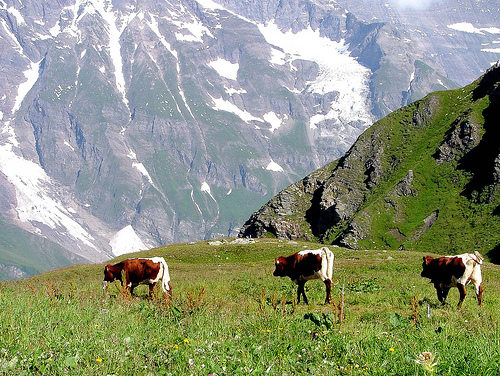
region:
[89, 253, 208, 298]
Cow grazing in the grass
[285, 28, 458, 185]
Snow on side of the mountain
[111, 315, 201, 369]
Flowers and weeds in the grass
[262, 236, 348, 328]
Brown and white cow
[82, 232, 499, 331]
Three cows walking in a row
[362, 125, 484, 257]
Hill is rocky with grass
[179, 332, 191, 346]
Yellow flower in the grass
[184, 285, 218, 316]
Dry weeds in the grass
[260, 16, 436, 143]
Snow in the crack of rocks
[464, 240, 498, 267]
Cow has a long tail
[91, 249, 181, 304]
a brown and white cow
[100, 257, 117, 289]
the head of a cow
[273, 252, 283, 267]
the ear of a cow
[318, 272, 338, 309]
the hind legs of a cow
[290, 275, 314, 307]
the front legs of a cow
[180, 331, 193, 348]
a yellow flower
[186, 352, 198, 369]
a white flower in the grass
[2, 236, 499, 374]
a green grassy field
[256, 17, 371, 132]
white snow on the mountain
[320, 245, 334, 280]
the tail of a cow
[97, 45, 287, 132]
the mountain is filled with snow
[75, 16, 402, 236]
the mountain is filled with snow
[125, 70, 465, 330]
the mountain is filled with snow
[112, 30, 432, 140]
the mountain is filled with snow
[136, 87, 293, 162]
the mountain is filled with snow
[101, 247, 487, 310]
the cows in the grass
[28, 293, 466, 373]
the grass, weeds and flowers on the ground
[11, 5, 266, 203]
the snow capped mountains in the background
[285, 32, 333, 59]
the snow on the mountain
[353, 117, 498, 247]
the mountain closest to the cows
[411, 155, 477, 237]
the greenery on the closest mountain to the cows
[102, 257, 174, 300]
the first cow facing left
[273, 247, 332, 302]
the second cow facing left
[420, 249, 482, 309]
the third cow facing left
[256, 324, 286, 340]
the yellow flowers on the ground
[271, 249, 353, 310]
white and brown cow